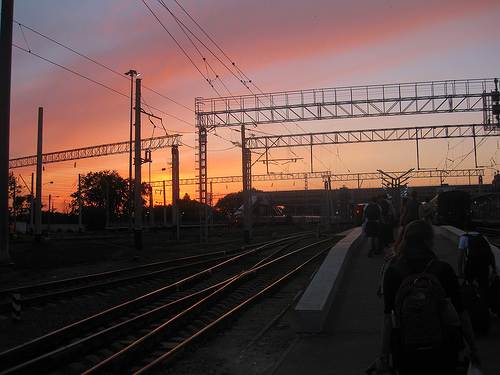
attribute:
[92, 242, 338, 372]
railroad — pictured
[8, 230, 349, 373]
railroad — pictured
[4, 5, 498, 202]
sky — multicolored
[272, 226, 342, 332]
concrete — gray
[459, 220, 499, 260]
shirt — white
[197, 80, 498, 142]
structure — metal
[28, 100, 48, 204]
pole — thick